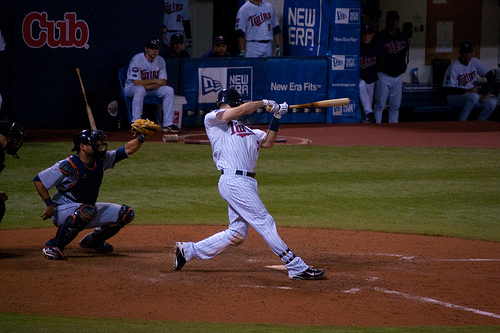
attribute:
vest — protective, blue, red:
[58, 148, 108, 196]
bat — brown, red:
[267, 91, 385, 142]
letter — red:
[25, 8, 94, 47]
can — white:
[161, 130, 184, 145]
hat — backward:
[212, 87, 250, 113]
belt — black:
[212, 168, 259, 184]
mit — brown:
[126, 105, 175, 137]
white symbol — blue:
[204, 62, 241, 102]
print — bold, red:
[18, 2, 100, 49]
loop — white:
[218, 163, 242, 182]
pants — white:
[172, 170, 327, 282]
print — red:
[226, 116, 272, 141]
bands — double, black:
[275, 244, 298, 262]